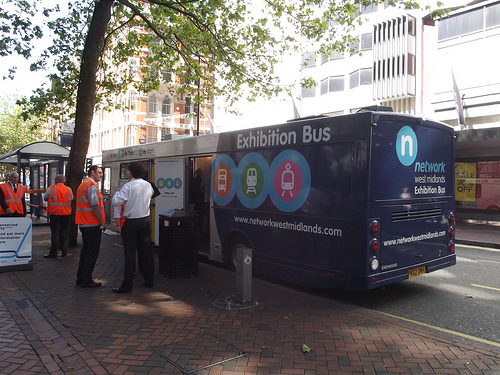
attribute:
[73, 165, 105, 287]
man — talking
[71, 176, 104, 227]
vest — orange, safety, bright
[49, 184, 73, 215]
vest — orange, safety, bright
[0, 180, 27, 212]
vest — orange, safety, bright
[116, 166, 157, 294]
man — talking, standing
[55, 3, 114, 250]
tree — large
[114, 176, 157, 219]
shirt — white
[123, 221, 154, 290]
pants — black